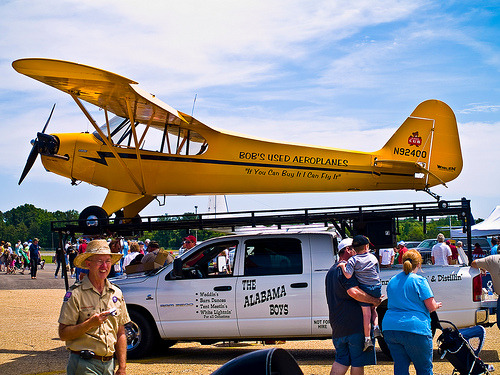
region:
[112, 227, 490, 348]
a silver pick up truck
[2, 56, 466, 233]
a bright yellow airplane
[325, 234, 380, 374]
a man holding child in arms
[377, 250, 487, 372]
a woman pushing stroller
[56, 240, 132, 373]
a man in brown uniform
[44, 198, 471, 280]
a black carrying rack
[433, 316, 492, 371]
a blue child's stroller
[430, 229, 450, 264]
a person standing in distance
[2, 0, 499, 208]
a cloudy blue sky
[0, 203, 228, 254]
tree range in distance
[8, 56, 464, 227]
a yellow plane on top of a truck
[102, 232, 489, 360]
a large, white pickup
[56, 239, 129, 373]
a man in a cowboy hat standing in front of the truck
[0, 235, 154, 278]
a crowd standing behind the truck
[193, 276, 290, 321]
black writing on the pickup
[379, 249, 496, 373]
a woman pushing a stroller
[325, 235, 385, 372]
a man carrying a child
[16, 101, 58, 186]
propeller on the airplane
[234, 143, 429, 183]
black writing on the plane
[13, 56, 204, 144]
yellow wing of the plane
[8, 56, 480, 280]
yellow airplane on display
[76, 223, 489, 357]
white pickup truck with letters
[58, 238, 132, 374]
man wearing straw hat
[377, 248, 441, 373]
woman wearing blue shirt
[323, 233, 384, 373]
little boy in man's arms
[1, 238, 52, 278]
large group of people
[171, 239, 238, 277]
open truck window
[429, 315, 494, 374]
top of blue stroller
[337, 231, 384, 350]
little boy wearing hat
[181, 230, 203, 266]
man wearing red hat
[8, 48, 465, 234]
bright yellow propeller plane with an advertisement on the side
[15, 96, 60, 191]
black plane propeller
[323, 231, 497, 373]
family of four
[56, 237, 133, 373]
man wearing a short sleeve uniform and hat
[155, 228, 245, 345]
driver's side door on a white trunk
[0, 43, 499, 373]
yellow plane attached to the top of a white truck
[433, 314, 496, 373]
blue baby stroller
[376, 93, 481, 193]
tail of a small airplane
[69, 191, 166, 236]
front wheels of a small airplane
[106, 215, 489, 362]
white truck with an advertisement on the side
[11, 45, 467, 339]
a plane on top of car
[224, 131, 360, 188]
a plane with lettering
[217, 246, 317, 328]
a truck with lettering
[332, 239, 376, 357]
a man holding a child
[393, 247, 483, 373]
a woman pushing a carriage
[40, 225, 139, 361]
a man with a brown shirt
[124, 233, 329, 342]
a silver pick up truck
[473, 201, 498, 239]
a small white tent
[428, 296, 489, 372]
a small blue stroller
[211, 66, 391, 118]
a cloudy blue sky